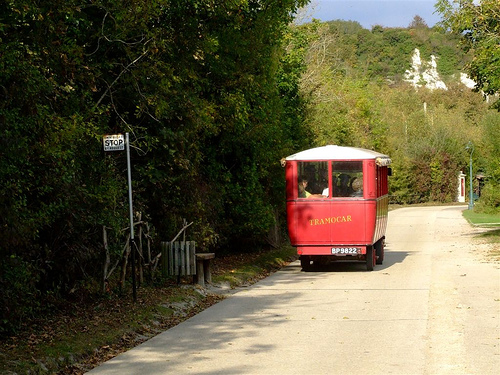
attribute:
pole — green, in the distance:
[459, 136, 477, 213]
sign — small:
[105, 131, 130, 149]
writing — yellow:
[299, 211, 362, 226]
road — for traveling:
[76, 199, 498, 374]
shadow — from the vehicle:
[300, 249, 423, 277]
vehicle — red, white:
[276, 139, 393, 274]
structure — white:
[405, 45, 425, 93]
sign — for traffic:
[94, 129, 188, 229]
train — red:
[272, 135, 399, 273]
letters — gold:
[307, 213, 354, 227]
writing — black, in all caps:
[100, 134, 124, 153]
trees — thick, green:
[154, 77, 254, 212]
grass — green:
[38, 277, 243, 372]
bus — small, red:
[285, 139, 402, 274]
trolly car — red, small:
[266, 135, 418, 285]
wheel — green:
[363, 242, 378, 271]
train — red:
[278, 138, 391, 275]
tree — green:
[51, 3, 270, 260]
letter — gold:
[309, 217, 315, 226]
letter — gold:
[312, 217, 319, 225]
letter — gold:
[317, 217, 324, 225]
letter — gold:
[330, 216, 337, 225]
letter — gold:
[345, 214, 352, 222]